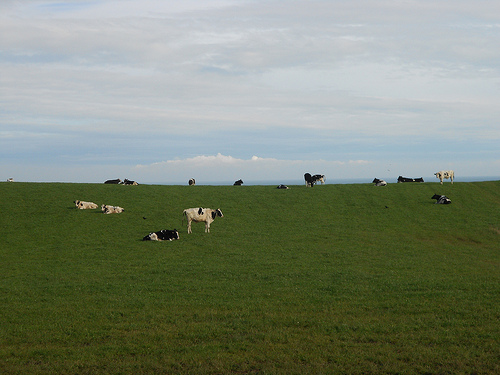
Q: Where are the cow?
A: Field.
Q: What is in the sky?
A: Clouds.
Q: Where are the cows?
A: In the field.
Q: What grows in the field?
A: Grass.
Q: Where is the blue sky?
A: Above the field.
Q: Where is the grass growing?
A: In the field.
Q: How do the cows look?
A: Black and white.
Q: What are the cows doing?
A: Grazing.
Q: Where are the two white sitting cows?
A: In the field.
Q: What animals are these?
A: Cows.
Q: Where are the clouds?
A: In the sky.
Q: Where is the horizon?
A: In the distance.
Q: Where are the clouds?
A: In the sky.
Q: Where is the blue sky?
A: Above the field.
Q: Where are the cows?
A: In the field.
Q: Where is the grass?
A: In the field.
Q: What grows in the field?
A: Grass.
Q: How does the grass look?
A: Short and green.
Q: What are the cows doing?
A: Grazing, sitting, and standing.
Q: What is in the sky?
A: Clouds.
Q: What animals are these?
A: Cows.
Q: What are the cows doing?
A: Eating.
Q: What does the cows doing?
A: Standing on grass.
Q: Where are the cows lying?
A: In field.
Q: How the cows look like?
A: Relaxed.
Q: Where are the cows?
A: On farm.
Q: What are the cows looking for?
A: Food.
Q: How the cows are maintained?
A: By farmer.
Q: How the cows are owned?
A: Dairy farm.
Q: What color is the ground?
A: Green.